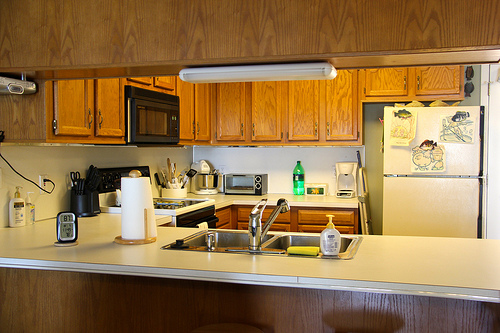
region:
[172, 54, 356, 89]
overhead white light fixture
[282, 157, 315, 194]
green clear soda bottle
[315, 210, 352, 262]
white soap container with yellow top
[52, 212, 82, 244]
black clock with silver trim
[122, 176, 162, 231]
white paper towel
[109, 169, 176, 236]
wooden paper towel holder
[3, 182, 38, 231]
bottle of white lotion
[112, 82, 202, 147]
black microwave with buttons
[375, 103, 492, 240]
white refrigerator with paper markings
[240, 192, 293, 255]
silver faucet in sink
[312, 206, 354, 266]
Container of liquid soap on sink.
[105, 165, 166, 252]
Paper towels in wooden holden.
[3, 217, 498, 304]
Paper towel holder on countertop.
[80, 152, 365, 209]
Coffee maker on countertop.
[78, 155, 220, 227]
Gas range has white top.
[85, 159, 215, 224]
Gas range has four burners.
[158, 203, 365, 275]
Sink is stainless steel.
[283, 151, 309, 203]
Bottle of soda on countertop.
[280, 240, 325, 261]
Yellow sponge on sink.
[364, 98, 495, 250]
White refrigerator has two doors.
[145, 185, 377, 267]
double sink set into counter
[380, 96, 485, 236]
drawings hanging from refrigerator door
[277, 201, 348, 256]
sponge and soap by sink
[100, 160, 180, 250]
paper towels in wooden holder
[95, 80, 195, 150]
black microwave underneath cabinet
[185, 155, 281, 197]
appliances against wall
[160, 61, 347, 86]
overhead light on bottom of cabinets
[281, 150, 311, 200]
green bottle of soda against wall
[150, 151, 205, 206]
utensils in round container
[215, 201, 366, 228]
wooden drawers below counters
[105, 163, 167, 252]
paper towel roll on a counter top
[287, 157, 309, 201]
a green bottle on a counter top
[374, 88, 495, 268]
a refrigerator in a kitchen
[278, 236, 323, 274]
a yellow sponge on a sink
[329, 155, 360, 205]
a coffee maker on a counter top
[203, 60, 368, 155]
brown cabinets on a wall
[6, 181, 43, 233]
two bottles on a counter top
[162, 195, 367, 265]
a sink in a kitchen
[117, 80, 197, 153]
a microwave oven next to cabinets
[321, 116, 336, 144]
a handle on a cabinet door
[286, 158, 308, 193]
A lime green soda bottle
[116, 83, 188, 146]
An over the stove microwave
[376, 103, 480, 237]
A white refrigerator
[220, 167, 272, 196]
A black and silver toaster oven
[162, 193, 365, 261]
A stainless steel kitchen faucet and sink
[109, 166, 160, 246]
Wooden paper towel roll holder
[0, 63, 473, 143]
Wooden cabinets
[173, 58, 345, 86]
White overhead light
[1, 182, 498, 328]
The kitchen counter top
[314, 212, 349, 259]
A disposable soap dispenser